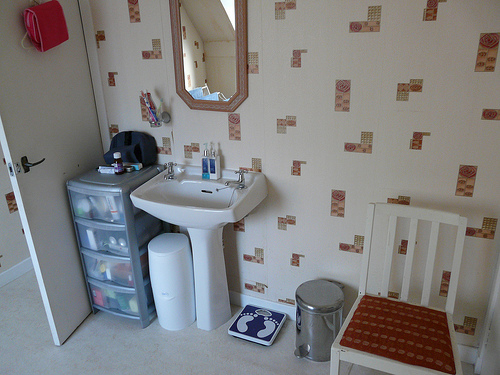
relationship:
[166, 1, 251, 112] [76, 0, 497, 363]
mirror hanging on wall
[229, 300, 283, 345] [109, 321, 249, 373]
scale on ground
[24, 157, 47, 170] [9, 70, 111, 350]
door handle on door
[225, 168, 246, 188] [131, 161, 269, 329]
knob on sink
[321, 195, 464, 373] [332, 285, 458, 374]
chair with red cushion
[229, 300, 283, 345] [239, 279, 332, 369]
scale has footprints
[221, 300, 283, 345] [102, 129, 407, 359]
scale near sink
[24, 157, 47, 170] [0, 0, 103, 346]
door handle on door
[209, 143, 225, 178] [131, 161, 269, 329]
bottle in sink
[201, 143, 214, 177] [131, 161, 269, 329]
bottle in sink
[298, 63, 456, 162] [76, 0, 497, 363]
wallpaper on wall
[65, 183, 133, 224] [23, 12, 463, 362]
drawer of storage unit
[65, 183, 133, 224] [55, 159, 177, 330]
drawer of storage unit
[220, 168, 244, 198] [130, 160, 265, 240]
faucet of sink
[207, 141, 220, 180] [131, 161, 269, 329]
soap on sink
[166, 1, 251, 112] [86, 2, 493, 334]
mirror on wall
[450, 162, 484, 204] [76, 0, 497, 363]
pattern on wall